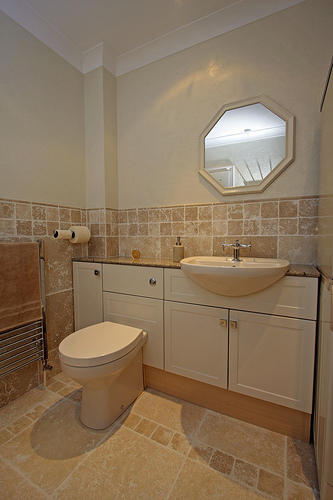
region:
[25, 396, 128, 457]
shadow of the toilet bowl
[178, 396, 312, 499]
shadow of the sink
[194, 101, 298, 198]
mirror with white frame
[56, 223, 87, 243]
two rolls of toilet paper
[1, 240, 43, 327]
light brown towel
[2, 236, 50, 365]
metal towel rack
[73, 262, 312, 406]
white cabinets in the bathroom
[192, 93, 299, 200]
A cream-colored mirror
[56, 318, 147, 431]
A cream toilet in a bathroom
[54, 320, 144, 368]
A cream toilet seat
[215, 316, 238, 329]
Knobs on a bathroom cabinet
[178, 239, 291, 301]
A cream sink hanging over a cabinet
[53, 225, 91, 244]
Two rolls of toilet paper on a wall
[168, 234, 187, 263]
A soap dispenser next to a sink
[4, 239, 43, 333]
A brown towel on a rack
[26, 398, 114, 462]
The shadow of a toilet on the floor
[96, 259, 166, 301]
A drawer in a bathroom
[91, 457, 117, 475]
white lines on the floor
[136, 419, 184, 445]
brown tiles on the bathroom floor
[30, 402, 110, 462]
toilet shadow on the ground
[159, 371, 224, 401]
brown base on the bottom of sink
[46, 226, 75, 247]
small toilet paper on roll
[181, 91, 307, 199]
oblong mirror on the wall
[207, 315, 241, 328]
brown handles on the cabinet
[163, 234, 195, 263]
brown soap holder on top of sink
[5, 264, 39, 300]
brown towel on the rack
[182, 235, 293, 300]
brown sink on top of counter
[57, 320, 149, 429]
a white porcelain toilet bowl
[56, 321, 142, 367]
a white plastic toilet seat lid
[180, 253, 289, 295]
a white porcelain bathroom sink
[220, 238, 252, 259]
a chrome bathroom sink faucet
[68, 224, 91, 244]
a full roll of toilet paper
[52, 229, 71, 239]
a small roll of toilet paper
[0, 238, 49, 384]
a chrome towel warmer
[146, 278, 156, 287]
a chrome toilet flush valve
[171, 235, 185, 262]
a small soap dispenser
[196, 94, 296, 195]
an octagonal vanity mirror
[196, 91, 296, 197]
octogonal shaped mirror frame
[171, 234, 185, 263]
pump top lotion dispenser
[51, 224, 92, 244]
two toilet paper rolls on dispensers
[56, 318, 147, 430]
oval shaped toilet and lid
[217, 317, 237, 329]
two square shaped cupboard handles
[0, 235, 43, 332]
rust colored bath towel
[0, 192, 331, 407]
multi-shaped tile wall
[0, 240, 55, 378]
metal towel hanging rack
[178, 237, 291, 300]
oval shaped sink and faucet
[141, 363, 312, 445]
wooden baseboard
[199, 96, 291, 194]
mirror above the sink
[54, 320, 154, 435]
beige toilet in the bathroom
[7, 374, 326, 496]
light brown flooring in the bathroom